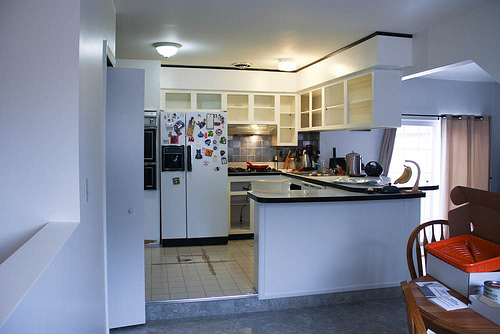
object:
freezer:
[162, 111, 229, 247]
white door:
[160, 112, 185, 239]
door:
[102, 68, 146, 331]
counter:
[228, 172, 440, 204]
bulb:
[156, 46, 177, 58]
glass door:
[388, 117, 445, 245]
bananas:
[394, 165, 412, 184]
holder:
[405, 160, 421, 192]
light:
[278, 58, 297, 71]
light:
[152, 42, 183, 60]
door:
[254, 93, 275, 121]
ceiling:
[117, 0, 500, 70]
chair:
[407, 220, 451, 280]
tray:
[424, 234, 500, 273]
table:
[407, 275, 500, 334]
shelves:
[116, 60, 401, 147]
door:
[191, 92, 228, 109]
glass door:
[299, 89, 323, 128]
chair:
[400, 282, 425, 334]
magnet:
[164, 113, 228, 172]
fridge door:
[185, 111, 228, 238]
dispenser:
[161, 145, 185, 170]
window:
[387, 110, 443, 237]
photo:
[173, 178, 180, 185]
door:
[345, 73, 372, 123]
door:
[323, 80, 346, 125]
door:
[224, 94, 249, 122]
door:
[276, 95, 296, 145]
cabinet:
[117, 59, 401, 146]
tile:
[144, 239, 256, 302]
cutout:
[470, 221, 474, 232]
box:
[425, 186, 499, 297]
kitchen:
[108, 30, 424, 304]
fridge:
[159, 110, 228, 245]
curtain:
[442, 108, 489, 241]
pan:
[424, 235, 500, 273]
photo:
[4, 4, 500, 334]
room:
[0, 0, 500, 334]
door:
[161, 91, 189, 110]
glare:
[168, 111, 221, 171]